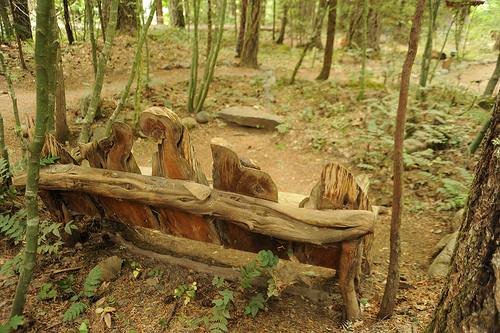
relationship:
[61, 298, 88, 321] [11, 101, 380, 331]
leaves behind bench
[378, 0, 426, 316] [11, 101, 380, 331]
trunk next to bench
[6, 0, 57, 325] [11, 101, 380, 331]
trunk behind bench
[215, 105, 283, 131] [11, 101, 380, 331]
rock in front of bench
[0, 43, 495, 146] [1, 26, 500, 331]
trail on ground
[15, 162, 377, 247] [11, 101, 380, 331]
log forms bench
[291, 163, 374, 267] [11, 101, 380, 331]
plank on bench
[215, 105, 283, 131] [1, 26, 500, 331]
rock on ground